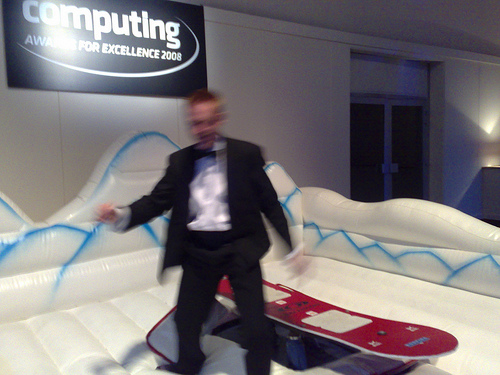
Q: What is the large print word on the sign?
A: Computing.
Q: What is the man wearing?
A: A tuxedo.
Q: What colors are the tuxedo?
A: Black and white.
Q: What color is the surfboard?
A: Red and white.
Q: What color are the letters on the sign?
A: White.